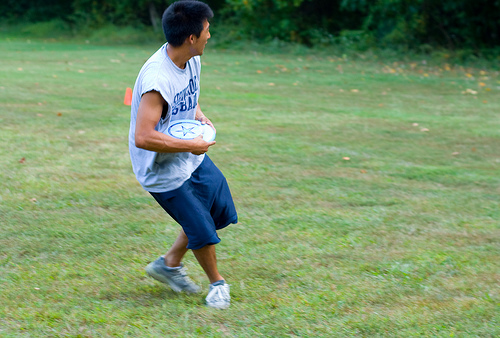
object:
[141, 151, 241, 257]
shorts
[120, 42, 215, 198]
shirt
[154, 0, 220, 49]
hair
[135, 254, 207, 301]
shoes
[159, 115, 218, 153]
frisbee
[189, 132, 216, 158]
hand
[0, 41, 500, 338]
grass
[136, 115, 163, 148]
skin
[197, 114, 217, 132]
hand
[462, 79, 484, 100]
leaves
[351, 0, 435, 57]
bush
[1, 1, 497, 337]
park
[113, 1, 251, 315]
guy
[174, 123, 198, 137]
star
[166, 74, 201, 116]
writing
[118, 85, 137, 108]
flag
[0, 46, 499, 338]
ground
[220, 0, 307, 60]
trees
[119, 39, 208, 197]
vest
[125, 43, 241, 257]
clothes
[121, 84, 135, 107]
cone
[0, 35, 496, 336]
field